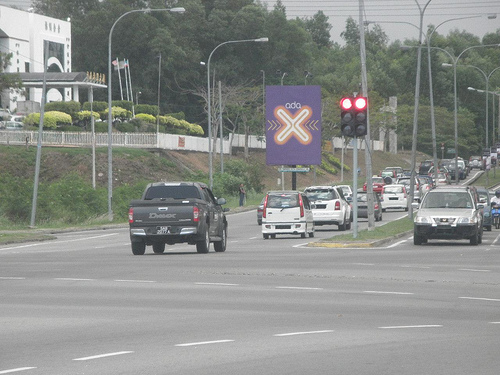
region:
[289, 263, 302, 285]
middle of a road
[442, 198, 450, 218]
edge of a car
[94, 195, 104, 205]
part of a hill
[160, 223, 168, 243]
back of a car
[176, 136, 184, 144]
part of a rail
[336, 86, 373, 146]
traffic signal shows red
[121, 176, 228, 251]
vehicle driving through intersection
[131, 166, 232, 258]
truck driving through intersection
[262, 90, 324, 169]
billboard with "x" on it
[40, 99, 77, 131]
yellow bush on hill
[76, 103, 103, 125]
yellow bush on hill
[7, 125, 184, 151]
white picket fence on hill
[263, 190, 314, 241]
white vehicle is stopped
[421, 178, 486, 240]
cars are stopped at intersection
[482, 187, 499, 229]
person riding a motorcycle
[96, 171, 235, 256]
truck going down the road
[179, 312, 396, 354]
white lines on the pavement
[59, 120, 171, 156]
white picket fence above the road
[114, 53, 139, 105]
flags in front of the building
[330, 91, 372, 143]
traffic light with red lit up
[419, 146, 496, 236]
car stopped at the intersection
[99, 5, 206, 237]
light post on the side of the road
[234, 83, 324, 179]
sign on the side of the road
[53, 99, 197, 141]
bushes in front of the building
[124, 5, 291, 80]
trees above the road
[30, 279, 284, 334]
The ground is made of asphalt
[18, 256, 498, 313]
The line in the street is white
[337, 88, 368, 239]
The traffic light is on red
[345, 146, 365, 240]
The pole is in the ground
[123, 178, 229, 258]
The truck is driving on the street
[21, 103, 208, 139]
The hydrangeas in the front of the building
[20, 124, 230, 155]
The fence is the color white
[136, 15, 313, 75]
The leaves on the tree are green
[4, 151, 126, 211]
The hill has grass growing out of it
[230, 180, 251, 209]
A person is standing on the side of the road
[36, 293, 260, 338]
The street is made of asphalt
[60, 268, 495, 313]
The lines in the street are white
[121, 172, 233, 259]
The truck is the color charcoal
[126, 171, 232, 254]
The truck is driving down the street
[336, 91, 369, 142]
The street light is on red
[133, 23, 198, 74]
The leaves on the tree are green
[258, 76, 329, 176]
The sign on the side of the street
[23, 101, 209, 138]
The hydrangeas in front of the building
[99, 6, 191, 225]
The street light in the ground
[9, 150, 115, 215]
The hill has grass growing